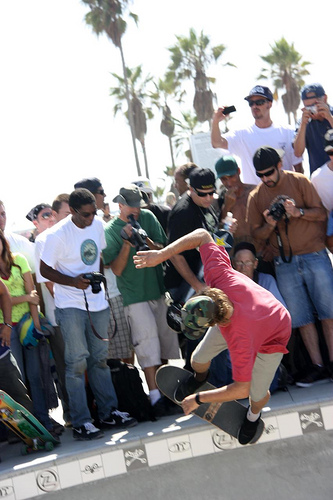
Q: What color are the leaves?
A: Green.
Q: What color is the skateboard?
A: Black.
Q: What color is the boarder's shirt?
A: Red.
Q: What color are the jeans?
A: Blue.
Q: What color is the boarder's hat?
A: Green.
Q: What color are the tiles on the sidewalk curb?
A: White.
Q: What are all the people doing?
A: Spectating a sporting event.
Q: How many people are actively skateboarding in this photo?
A: One.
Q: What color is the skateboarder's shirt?
A: Red.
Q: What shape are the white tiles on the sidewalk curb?
A: Square.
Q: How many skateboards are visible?
A: Two.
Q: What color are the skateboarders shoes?
A: Black.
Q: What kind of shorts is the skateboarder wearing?
A: Khaki shorts.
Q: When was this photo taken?
A: Outside, during the daytime.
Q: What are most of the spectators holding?
A: Cameras.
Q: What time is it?
A: Afternoon.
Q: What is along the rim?
A: Row of tiles.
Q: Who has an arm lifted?
A: Skater.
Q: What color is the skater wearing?
A: Red.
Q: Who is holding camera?
A: A man.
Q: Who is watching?
A: A crowd.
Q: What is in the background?
A: Trees.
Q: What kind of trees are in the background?
A: Palm trees.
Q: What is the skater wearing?
A: A hat.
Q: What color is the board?
A: Black.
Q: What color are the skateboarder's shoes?
A: Black.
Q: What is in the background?
A: Trees.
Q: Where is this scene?
A: At a skatepark.